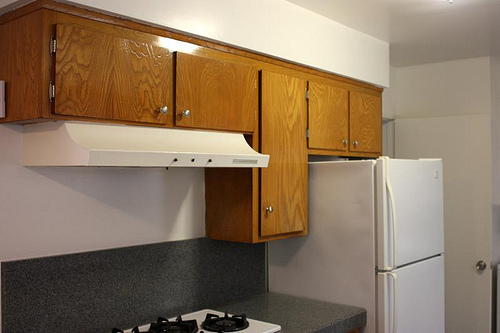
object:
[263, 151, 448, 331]
refrigerator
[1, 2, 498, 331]
kitchen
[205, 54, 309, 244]
cabinet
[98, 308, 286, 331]
stovetop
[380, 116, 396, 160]
air vent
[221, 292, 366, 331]
countertop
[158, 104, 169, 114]
knob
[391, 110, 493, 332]
door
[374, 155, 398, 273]
handle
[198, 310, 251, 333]
burner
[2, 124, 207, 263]
wall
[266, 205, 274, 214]
knob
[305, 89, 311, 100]
hinge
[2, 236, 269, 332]
trim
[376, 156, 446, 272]
door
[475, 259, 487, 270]
knob